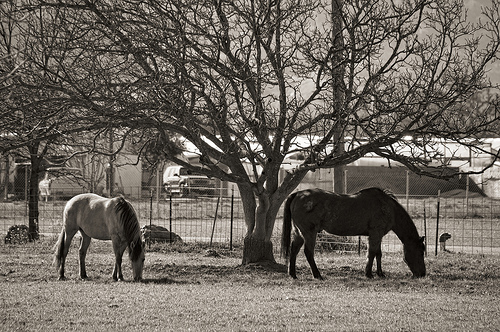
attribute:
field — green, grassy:
[6, 230, 498, 328]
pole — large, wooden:
[320, 3, 365, 206]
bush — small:
[5, 220, 35, 244]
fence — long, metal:
[10, 182, 497, 262]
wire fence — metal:
[0, 185, 499, 258]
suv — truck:
[155, 158, 225, 196]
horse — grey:
[51, 193, 147, 281]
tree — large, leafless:
[1, 0, 497, 266]